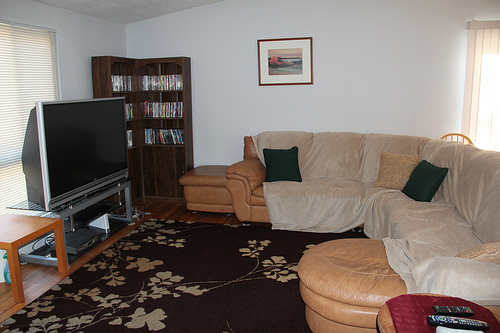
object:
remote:
[431, 304, 476, 316]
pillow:
[400, 158, 450, 203]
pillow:
[454, 242, 499, 262]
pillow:
[261, 145, 302, 183]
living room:
[0, 0, 499, 333]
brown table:
[0, 213, 67, 305]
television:
[20, 96, 129, 212]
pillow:
[374, 150, 423, 192]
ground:
[134, 199, 235, 221]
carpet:
[0, 217, 374, 332]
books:
[140, 72, 183, 90]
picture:
[256, 36, 314, 86]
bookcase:
[91, 55, 145, 205]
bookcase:
[137, 56, 193, 197]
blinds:
[0, 21, 59, 213]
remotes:
[425, 313, 490, 331]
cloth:
[383, 293, 499, 333]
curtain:
[460, 20, 499, 152]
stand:
[6, 178, 134, 269]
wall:
[127, 3, 462, 131]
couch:
[223, 130, 499, 332]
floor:
[3, 192, 366, 333]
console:
[85, 212, 131, 234]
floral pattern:
[59, 272, 107, 302]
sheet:
[250, 131, 499, 306]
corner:
[120, 25, 137, 56]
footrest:
[178, 164, 235, 216]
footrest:
[297, 238, 421, 332]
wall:
[59, 10, 94, 94]